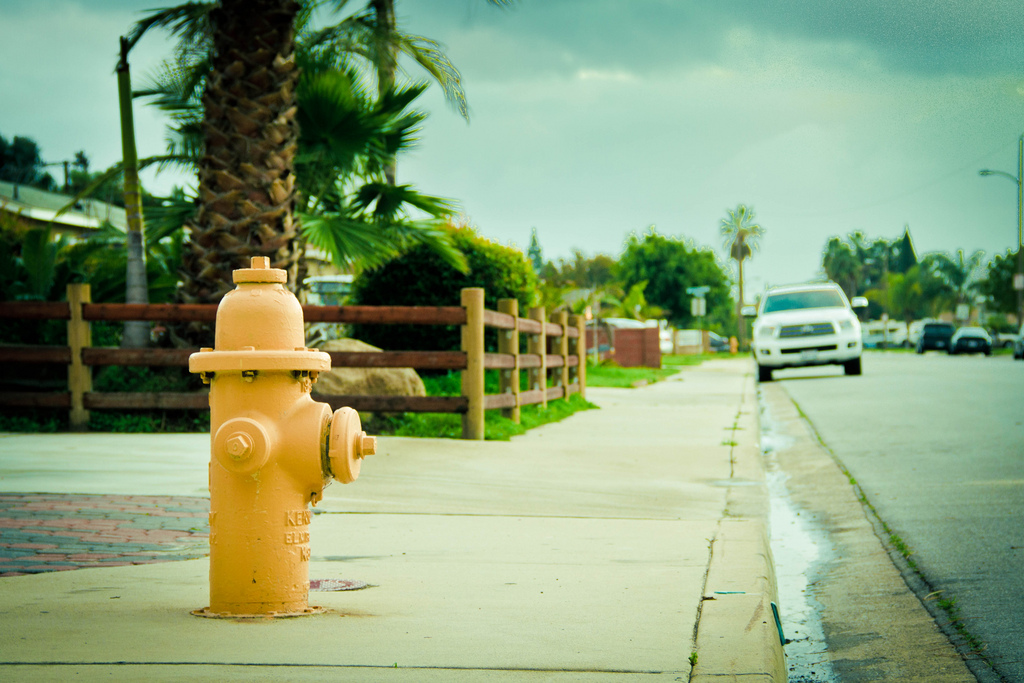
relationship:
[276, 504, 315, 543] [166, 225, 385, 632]
letters on fire hydrant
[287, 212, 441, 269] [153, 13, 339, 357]
leaves on tree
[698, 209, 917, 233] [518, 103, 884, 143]
dark storm clouds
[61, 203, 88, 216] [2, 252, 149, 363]
roof of a home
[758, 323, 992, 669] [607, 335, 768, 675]
street next to sidewalk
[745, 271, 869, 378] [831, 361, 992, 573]
truck parked street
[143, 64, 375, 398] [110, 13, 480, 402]
trunk of tree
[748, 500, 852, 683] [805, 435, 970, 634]
water on ground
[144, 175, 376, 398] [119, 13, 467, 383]
trunk of tree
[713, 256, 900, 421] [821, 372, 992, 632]
truck on street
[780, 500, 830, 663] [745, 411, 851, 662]
water in gutter